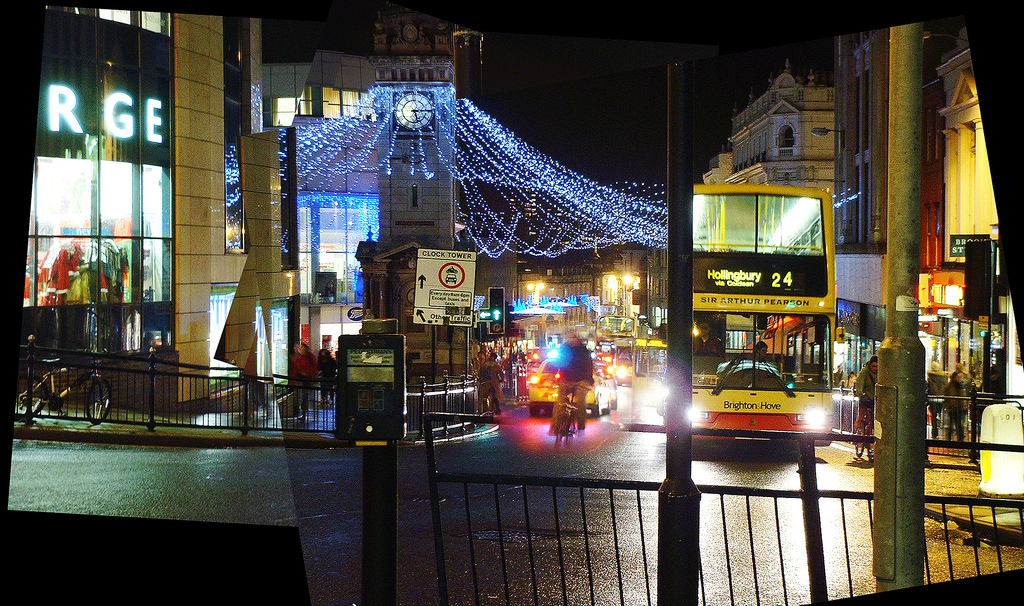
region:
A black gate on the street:
[428, 416, 644, 604]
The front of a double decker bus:
[689, 185, 844, 445]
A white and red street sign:
[418, 245, 480, 328]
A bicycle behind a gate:
[16, 362, 118, 419]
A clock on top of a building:
[389, 93, 441, 129]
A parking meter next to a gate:
[320, 330, 426, 605]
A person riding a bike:
[539, 333, 606, 442]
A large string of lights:
[283, 91, 663, 269]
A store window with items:
[29, 160, 181, 309]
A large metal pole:
[873, 21, 921, 585]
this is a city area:
[90, 57, 956, 528]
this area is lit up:
[67, 57, 707, 513]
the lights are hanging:
[286, 83, 660, 340]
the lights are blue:
[254, 95, 727, 408]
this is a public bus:
[318, 72, 906, 581]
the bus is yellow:
[626, 119, 877, 455]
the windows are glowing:
[667, 189, 819, 259]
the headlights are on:
[617, 303, 932, 569]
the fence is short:
[418, 473, 780, 590]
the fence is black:
[406, 423, 698, 595]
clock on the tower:
[378, 83, 440, 137]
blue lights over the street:
[268, 80, 657, 255]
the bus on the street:
[666, 162, 854, 453]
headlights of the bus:
[676, 393, 836, 438]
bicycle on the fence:
[18, 351, 124, 425]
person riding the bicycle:
[528, 326, 602, 459]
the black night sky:
[483, 22, 747, 187]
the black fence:
[31, 341, 484, 437]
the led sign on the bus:
[696, 257, 827, 292]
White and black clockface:
[389, 82, 435, 137]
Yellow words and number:
[699, 258, 808, 291]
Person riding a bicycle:
[543, 333, 605, 448]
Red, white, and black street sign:
[411, 239, 479, 335]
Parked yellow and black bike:
[12, 349, 137, 427]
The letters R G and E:
[47, 69, 178, 159]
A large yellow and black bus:
[689, 178, 846, 467]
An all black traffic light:
[954, 227, 1000, 323]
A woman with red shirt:
[287, 337, 317, 424]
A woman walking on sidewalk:
[283, 337, 323, 429]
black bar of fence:
[422, 471, 458, 599]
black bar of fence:
[452, 476, 487, 593]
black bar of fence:
[486, 481, 516, 602]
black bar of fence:
[512, 477, 542, 599]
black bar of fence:
[543, 481, 575, 598]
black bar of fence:
[575, 484, 596, 598]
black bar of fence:
[603, 484, 627, 599]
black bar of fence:
[632, 486, 655, 603]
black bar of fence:
[716, 486, 737, 604]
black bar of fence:
[740, 490, 759, 602]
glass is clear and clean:
[693, 195, 754, 253]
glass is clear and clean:
[97, 160, 133, 231]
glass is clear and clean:
[37, 156, 89, 227]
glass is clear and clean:
[94, 239, 127, 296]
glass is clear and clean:
[141, 236, 171, 297]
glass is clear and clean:
[143, 8, 173, 37]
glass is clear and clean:
[94, 8, 129, 24]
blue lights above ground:
[256, 60, 642, 285]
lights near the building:
[262, 69, 656, 286]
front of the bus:
[593, 187, 870, 483]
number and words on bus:
[666, 244, 825, 336]